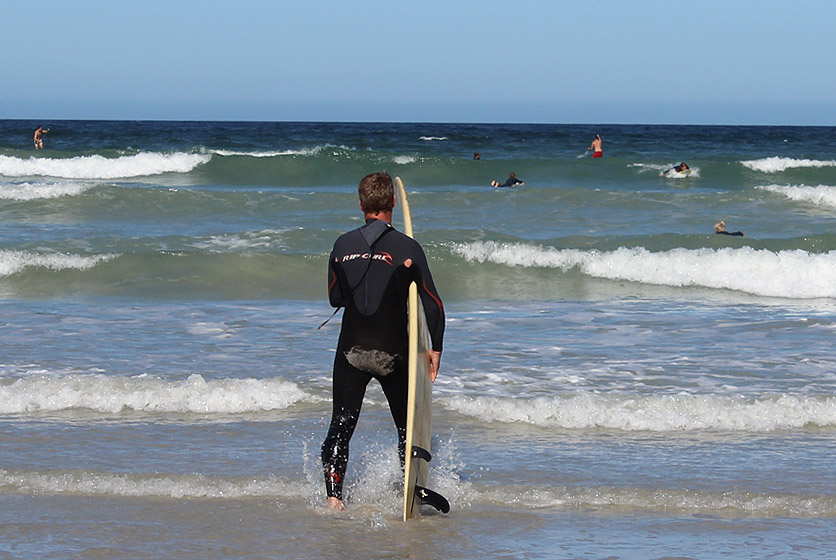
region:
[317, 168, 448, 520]
Man holding surfboard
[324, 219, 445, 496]
a black wet suit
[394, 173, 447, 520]
A white surfboard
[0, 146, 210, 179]
the wave is white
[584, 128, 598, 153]
a man with red shorts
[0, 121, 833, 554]
the water is blue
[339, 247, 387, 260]
white letters on back of wetsuit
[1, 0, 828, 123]
the sky is clear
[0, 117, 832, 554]
people are swimming in the water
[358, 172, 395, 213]
the man has brown hair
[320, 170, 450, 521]
man holding surfboard walking into the ocean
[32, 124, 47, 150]
surfer riding wave in the ocean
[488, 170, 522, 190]
surfer paddling out into a wave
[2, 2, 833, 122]
Blue sky on a beautiful day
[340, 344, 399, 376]
Sand stuck to the buttocks of a surfboarder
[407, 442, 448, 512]
surfboard fins used to control the board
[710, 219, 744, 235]
woman with a bun paddling out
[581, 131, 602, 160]
man in red shorts riding a stand up paddle board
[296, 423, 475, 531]
water splashing on a surfers feet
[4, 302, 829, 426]
sea foam settles as the wave reaches the shore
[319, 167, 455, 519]
A man holding a surfboard.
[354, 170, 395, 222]
A man with hair on his head.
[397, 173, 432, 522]
A man holding a surfboard.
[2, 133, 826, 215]
A wave in the ocean.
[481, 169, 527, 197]
A man on a surfboard.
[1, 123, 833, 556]
A large body of water.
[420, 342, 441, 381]
A right human hand.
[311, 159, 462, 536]
a man carrying a surf board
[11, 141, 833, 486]
waves in the water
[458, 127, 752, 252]
people swimming in the water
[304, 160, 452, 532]
a man in a wet suit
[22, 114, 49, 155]
a person surfing in the water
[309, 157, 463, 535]
a man walking into the water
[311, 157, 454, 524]
a man standing in the water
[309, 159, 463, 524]
a man walking towards the water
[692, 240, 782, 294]
water is white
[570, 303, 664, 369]
small waves in the water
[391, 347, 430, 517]
a surfboard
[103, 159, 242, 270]
waves in the ocean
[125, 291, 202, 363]
the water is dark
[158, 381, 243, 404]
water is white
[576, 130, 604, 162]
person in the water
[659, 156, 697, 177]
a person surfing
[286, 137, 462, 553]
man looking at ocean waves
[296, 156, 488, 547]
man wearing black wetsuit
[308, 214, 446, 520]
black wetsuit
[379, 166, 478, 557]
white wooden surfboard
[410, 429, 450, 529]
black fins on surfboard